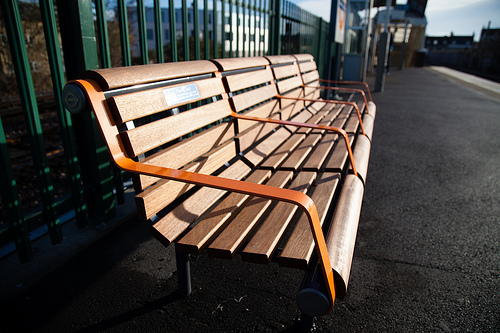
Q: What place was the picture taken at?
A: It was taken at the street.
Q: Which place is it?
A: It is a street.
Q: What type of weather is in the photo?
A: It is cloudy.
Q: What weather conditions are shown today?
A: It is cloudy.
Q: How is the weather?
A: It is cloudy.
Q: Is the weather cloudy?
A: Yes, it is cloudy.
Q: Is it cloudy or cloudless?
A: It is cloudy.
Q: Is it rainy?
A: No, it is cloudy.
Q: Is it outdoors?
A: Yes, it is outdoors.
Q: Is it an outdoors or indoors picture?
A: It is outdoors.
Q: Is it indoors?
A: No, it is outdoors.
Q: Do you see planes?
A: No, there are no planes.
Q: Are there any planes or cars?
A: No, there are no planes or cars.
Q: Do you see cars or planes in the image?
A: No, there are no planes or cars.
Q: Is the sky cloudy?
A: Yes, the sky is cloudy.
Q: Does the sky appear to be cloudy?
A: Yes, the sky is cloudy.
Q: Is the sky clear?
A: No, the sky is cloudy.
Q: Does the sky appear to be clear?
A: No, the sky is cloudy.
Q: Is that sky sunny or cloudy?
A: The sky is cloudy.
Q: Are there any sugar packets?
A: No, there are no sugar packets.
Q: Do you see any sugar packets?
A: No, there are no sugar packets.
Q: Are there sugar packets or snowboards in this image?
A: No, there are no sugar packets or snowboards.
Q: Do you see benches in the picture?
A: Yes, there is a bench.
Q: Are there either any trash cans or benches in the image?
A: Yes, there is a bench.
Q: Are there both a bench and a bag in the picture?
A: No, there is a bench but no bags.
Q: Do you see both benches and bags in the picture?
A: No, there is a bench but no bags.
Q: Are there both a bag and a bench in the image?
A: No, there is a bench but no bags.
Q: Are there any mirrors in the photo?
A: No, there are no mirrors.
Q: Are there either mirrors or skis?
A: No, there are no mirrors or skis.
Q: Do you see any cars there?
A: No, there are no cars.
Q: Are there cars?
A: No, there are no cars.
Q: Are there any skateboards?
A: No, there are no skateboards.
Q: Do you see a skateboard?
A: No, there are no skateboards.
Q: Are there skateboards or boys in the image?
A: No, there are no skateboards or boys.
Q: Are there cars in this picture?
A: No, there are no cars.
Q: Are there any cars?
A: No, there are no cars.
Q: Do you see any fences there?
A: Yes, there is a fence.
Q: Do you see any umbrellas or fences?
A: Yes, there is a fence.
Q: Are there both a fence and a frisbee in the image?
A: No, there is a fence but no frisbees.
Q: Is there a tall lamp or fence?
A: Yes, there is a tall fence.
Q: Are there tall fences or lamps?
A: Yes, there is a tall fence.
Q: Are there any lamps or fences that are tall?
A: Yes, the fence is tall.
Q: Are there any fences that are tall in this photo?
A: Yes, there is a tall fence.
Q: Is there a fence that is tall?
A: Yes, there is a fence that is tall.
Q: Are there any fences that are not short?
A: Yes, there is a tall fence.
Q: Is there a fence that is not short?
A: Yes, there is a tall fence.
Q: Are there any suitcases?
A: No, there are no suitcases.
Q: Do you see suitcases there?
A: No, there are no suitcases.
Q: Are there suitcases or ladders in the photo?
A: No, there are no suitcases or ladders.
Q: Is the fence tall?
A: Yes, the fence is tall.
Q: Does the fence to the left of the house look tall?
A: Yes, the fence is tall.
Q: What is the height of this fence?
A: The fence is tall.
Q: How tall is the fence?
A: The fence is tall.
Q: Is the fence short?
A: No, the fence is tall.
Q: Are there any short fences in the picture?
A: No, there is a fence but it is tall.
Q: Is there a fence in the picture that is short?
A: No, there is a fence but it is tall.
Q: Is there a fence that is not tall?
A: No, there is a fence but it is tall.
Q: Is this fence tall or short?
A: The fence is tall.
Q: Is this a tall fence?
A: Yes, this is a tall fence.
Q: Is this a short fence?
A: No, this is a tall fence.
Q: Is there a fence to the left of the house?
A: Yes, there is a fence to the left of the house.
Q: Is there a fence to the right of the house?
A: No, the fence is to the left of the house.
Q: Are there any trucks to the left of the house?
A: No, there is a fence to the left of the house.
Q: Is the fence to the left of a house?
A: Yes, the fence is to the left of a house.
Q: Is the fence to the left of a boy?
A: No, the fence is to the left of a house.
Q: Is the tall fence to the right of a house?
A: No, the fence is to the left of a house.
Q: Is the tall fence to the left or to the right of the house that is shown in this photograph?
A: The fence is to the left of the house.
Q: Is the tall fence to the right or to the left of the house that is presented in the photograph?
A: The fence is to the left of the house.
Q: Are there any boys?
A: No, there are no boys.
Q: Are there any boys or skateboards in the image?
A: No, there are no boys or skateboards.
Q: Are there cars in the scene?
A: No, there are no cars.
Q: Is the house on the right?
A: Yes, the house is on the right of the image.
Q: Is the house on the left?
A: No, the house is on the right of the image.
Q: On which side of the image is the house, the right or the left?
A: The house is on the right of the image.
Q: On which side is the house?
A: The house is on the right of the image.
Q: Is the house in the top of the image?
A: Yes, the house is in the top of the image.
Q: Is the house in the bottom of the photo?
A: No, the house is in the top of the image.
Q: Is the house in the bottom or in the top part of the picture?
A: The house is in the top of the image.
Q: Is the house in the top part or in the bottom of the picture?
A: The house is in the top of the image.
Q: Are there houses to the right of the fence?
A: Yes, there is a house to the right of the fence.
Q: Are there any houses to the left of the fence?
A: No, the house is to the right of the fence.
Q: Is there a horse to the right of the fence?
A: No, there is a house to the right of the fence.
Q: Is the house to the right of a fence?
A: Yes, the house is to the right of a fence.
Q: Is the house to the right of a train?
A: No, the house is to the right of a fence.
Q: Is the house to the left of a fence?
A: No, the house is to the right of a fence.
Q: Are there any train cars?
A: No, there are no train cars.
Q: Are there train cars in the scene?
A: No, there are no train cars.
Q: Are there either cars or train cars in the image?
A: No, there are no train cars or cars.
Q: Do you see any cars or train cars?
A: No, there are no train cars or cars.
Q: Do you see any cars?
A: No, there are no cars.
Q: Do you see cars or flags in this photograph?
A: No, there are no cars or flags.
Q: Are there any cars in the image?
A: No, there are no cars.